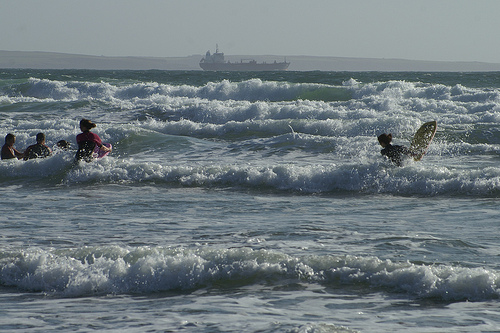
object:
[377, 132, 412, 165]
person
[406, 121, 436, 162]
boogie board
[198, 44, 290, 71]
ship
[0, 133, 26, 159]
people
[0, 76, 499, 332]
water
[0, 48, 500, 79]
shore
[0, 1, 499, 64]
sky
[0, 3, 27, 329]
left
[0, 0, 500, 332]
background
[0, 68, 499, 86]
water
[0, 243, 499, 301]
wave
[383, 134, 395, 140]
ponytail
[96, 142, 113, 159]
surfboard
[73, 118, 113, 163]
woman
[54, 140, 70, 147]
man